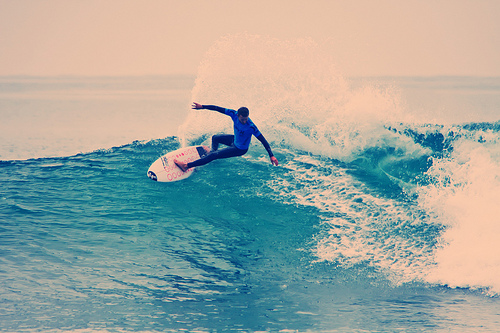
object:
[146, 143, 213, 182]
board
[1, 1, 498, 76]
skies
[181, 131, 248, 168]
pants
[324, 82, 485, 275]
surf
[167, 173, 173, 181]
red lettering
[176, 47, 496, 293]
splash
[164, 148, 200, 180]
pink rings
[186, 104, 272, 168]
wet suit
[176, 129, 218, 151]
surboard spray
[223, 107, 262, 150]
shirt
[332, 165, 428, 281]
foam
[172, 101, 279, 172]
man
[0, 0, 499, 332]
blue waters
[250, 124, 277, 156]
arm